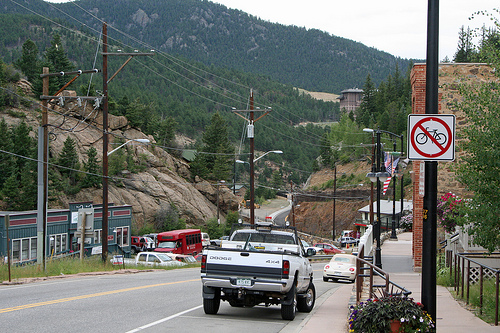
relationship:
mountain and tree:
[178, 1, 352, 88] [221, 77, 256, 110]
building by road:
[4, 190, 140, 267] [103, 265, 164, 301]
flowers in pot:
[355, 288, 435, 331] [378, 318, 408, 333]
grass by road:
[53, 254, 94, 272] [103, 265, 164, 301]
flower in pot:
[367, 288, 390, 314] [378, 318, 408, 333]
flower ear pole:
[367, 288, 390, 314] [407, 0, 465, 326]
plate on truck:
[226, 276, 266, 296] [199, 217, 323, 303]